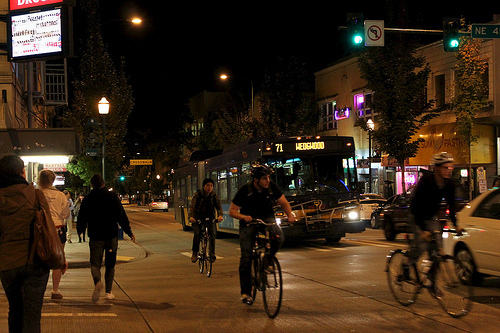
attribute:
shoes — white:
[83, 281, 118, 300]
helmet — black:
[250, 165, 272, 178]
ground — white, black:
[416, 160, 457, 192]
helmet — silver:
[432, 151, 456, 168]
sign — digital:
[291, 135, 331, 155]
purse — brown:
[28, 195, 74, 268]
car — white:
[428, 189, 499, 281]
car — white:
[408, 152, 498, 307]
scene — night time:
[38, 177, 495, 323]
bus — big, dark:
[170, 132, 367, 245]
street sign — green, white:
[468, 21, 498, 40]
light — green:
[347, 27, 364, 48]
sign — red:
[361, 17, 388, 47]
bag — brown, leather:
[28, 185, 64, 270]